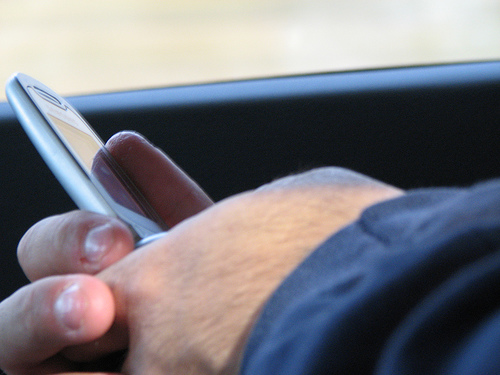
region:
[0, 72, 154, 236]
outdated silver flip cellphone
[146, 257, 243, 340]
back of a hairy hand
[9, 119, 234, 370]
man's hand holding cellphone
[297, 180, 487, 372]
blue gray sweatshirt sleeve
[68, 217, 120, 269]
short bitten fingernails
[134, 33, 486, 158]
car door window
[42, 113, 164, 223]
cellphone screen of old flip phone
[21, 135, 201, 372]
clasping fingers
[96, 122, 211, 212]
man's thumb touching phone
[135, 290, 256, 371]
black hair on back of man's hand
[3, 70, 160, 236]
a silver cell phone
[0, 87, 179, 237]
an older model flip phone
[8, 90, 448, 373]
a man's hand holding a cell phone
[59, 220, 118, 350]
short bitten fingernails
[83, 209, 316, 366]
the back of a hand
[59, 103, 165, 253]
fingers holding a cell phone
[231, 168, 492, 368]
a grey blue sweatshirt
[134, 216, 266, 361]
black hair on a hand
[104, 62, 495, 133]
car door window ledge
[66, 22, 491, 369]
man sitting in car looking at phone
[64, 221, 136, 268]
Small wound at bottom of fingernail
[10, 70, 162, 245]
Cell phone being used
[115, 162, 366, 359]
Man has dark hair on his hand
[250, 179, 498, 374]
Blue sleeve of shirt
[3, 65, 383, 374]
Man is holding a cell phone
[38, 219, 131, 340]
Fingernails are extremely short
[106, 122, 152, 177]
Dry skin on thumb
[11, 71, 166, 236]
Cell phone is on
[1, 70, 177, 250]
Cell phone is gray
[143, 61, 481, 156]
Black upholstered support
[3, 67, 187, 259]
silver cellular phone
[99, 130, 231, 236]
man's white thumb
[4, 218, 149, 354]
man's fingers with bitten nails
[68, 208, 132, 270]
bitten fingernails with sore cuticles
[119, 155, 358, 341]
man's hairy hand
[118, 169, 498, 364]
man's hand in a blue jacket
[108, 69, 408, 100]
windowsill of a car window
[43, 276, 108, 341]
bitten fingernail on the middle finger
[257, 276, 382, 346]
navy jacket cuff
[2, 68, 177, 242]
silver cell phone with a touch screen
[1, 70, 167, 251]
Cell phone on hand of person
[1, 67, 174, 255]
Phone is color silver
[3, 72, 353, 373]
Cell phone on hand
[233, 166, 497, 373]
Person wearing a long sleeve jacket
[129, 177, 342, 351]
Black hair on hand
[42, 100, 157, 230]
Screen of phone is small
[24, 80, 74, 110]
Microphone of phone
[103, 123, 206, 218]
Thumb holds one side of phone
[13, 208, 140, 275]
Index finger holds left side of clock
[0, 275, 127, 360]
Middle finger